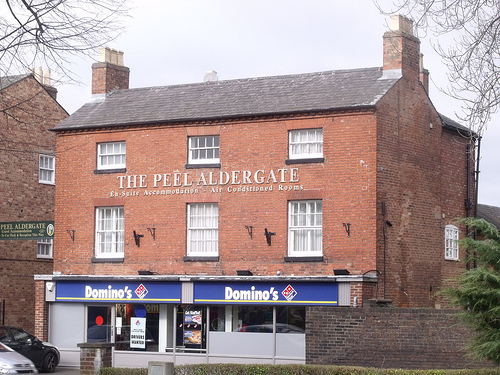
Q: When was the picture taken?
A: Daytime.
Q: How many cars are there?
A: Two.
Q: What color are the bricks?
A: Red.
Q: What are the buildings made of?
A: Bricks.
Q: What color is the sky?
A: Gray.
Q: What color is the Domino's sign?
A: Blue.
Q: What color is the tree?
A: Green.